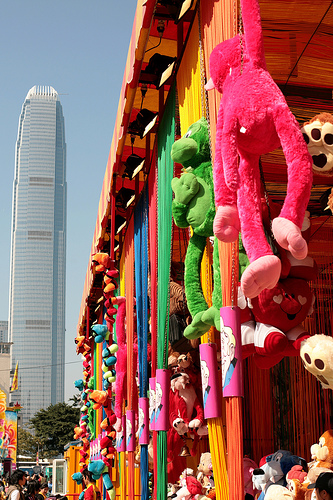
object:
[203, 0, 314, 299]
monkey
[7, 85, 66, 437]
building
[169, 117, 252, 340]
monkey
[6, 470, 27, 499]
man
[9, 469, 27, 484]
hair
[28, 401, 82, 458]
tree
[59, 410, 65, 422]
leaves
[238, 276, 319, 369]
stuffed animal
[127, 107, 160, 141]
light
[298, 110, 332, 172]
paw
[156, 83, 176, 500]
curtain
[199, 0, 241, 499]
curtain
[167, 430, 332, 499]
stand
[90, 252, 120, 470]
snake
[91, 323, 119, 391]
snake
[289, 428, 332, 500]
stuffed animals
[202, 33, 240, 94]
heart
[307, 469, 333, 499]
person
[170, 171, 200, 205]
paw